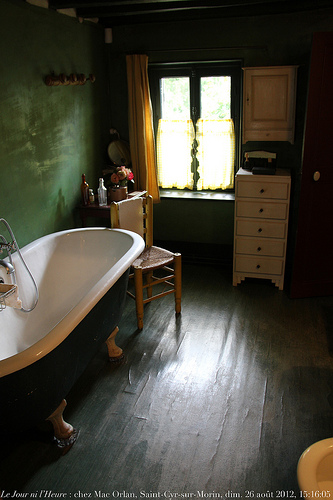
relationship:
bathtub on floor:
[1, 227, 146, 449] [176, 408, 252, 475]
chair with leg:
[110, 194, 181, 330] [171, 252, 181, 314]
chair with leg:
[110, 194, 181, 330] [132, 264, 144, 330]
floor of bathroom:
[0, 259, 332, 499] [0, 0, 332, 498]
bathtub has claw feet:
[1, 227, 146, 449] [47, 399, 81, 449]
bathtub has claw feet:
[1, 227, 146, 449] [105, 323, 122, 356]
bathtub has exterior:
[10, 221, 162, 427] [10, 44, 102, 213]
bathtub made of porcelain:
[1, 227, 146, 449] [7, 211, 195, 449]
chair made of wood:
[110, 194, 181, 330] [134, 248, 201, 327]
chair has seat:
[107, 192, 185, 330] [129, 242, 175, 270]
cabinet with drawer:
[206, 178, 298, 312] [235, 180, 288, 198]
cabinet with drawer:
[206, 178, 298, 312] [234, 197, 286, 216]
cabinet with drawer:
[206, 178, 298, 312] [235, 218, 285, 237]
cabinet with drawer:
[206, 178, 298, 312] [234, 236, 283, 255]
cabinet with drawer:
[206, 178, 298, 312] [235, 253, 282, 275]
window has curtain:
[146, 65, 238, 190] [154, 116, 195, 189]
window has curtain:
[146, 65, 238, 190] [194, 115, 237, 190]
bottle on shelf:
[95, 174, 108, 207] [83, 118, 166, 251]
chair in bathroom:
[110, 194, 181, 330] [0, 1, 330, 498]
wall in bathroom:
[0, 0, 115, 259] [0, 1, 330, 498]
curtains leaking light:
[155, 118, 235, 185] [161, 75, 228, 189]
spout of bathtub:
[1, 250, 16, 274] [1, 227, 146, 449]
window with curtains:
[148, 61, 240, 191] [154, 82, 254, 172]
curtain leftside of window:
[117, 70, 163, 212] [154, 78, 234, 203]